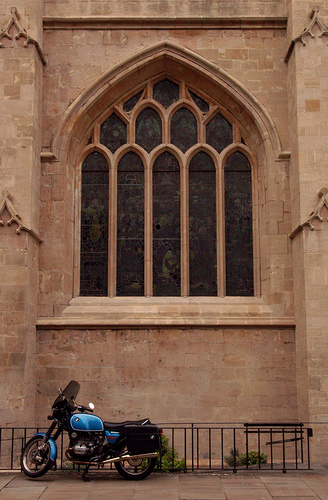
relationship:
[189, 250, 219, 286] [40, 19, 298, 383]
window on building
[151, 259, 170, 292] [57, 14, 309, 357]
window on building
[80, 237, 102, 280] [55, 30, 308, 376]
window on building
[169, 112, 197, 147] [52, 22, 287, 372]
window on building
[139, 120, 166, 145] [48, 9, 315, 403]
window on building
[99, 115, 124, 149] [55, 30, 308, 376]
window on building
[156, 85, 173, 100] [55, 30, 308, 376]
window on building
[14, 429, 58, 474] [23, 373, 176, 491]
tire of a motorcycle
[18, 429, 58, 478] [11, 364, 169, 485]
tire of a motorcycle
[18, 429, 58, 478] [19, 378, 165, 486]
tire of a motorcycle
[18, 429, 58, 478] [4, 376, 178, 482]
tire of a motorcycle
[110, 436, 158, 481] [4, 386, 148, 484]
tire of a motorcycle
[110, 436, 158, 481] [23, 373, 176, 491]
tire of a motorcycle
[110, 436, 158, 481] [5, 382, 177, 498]
tire of a motorcycle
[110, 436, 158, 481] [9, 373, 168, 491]
tire of a motorcycle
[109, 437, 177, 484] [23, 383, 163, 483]
tire of a motorcycle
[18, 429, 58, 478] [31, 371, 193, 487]
tire of a motorcycle